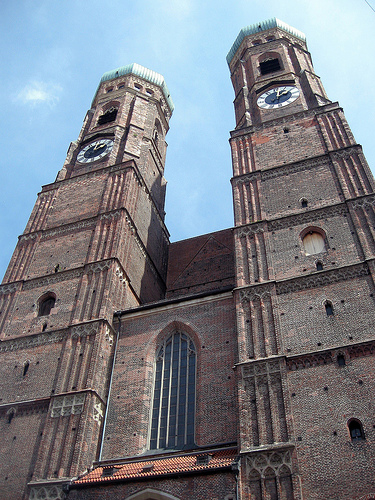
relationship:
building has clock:
[1, 18, 372, 500] [75, 138, 115, 163]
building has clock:
[1, 18, 372, 500] [256, 86, 299, 111]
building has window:
[1, 18, 372, 500] [144, 328, 200, 450]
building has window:
[1, 18, 372, 500] [38, 296, 55, 315]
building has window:
[1, 18, 372, 500] [348, 421, 364, 442]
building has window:
[1, 18, 372, 500] [336, 352, 346, 367]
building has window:
[1, 18, 372, 500] [324, 299, 335, 317]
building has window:
[1, 18, 372, 500] [316, 259, 324, 272]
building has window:
[1, 18, 372, 500] [300, 198, 309, 208]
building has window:
[1, 18, 372, 500] [283, 126, 290, 134]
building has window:
[1, 18, 372, 500] [256, 59, 284, 75]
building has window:
[1, 18, 372, 500] [7, 408, 15, 425]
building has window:
[1, 18, 372, 500] [22, 361, 30, 379]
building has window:
[1, 18, 372, 500] [40, 322, 50, 333]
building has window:
[1, 18, 372, 500] [53, 263, 61, 272]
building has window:
[1, 18, 372, 500] [96, 108, 118, 125]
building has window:
[1, 18, 372, 500] [153, 131, 161, 150]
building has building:
[1, 18, 372, 500] [1, 18, 374, 500]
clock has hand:
[75, 138, 115, 163] [94, 140, 100, 151]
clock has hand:
[256, 86, 299, 111] [278, 88, 291, 96]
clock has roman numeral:
[75, 138, 115, 163] [79, 157, 85, 163]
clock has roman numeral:
[256, 86, 299, 111] [267, 103, 274, 108]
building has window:
[1, 18, 374, 500] [119, 82, 127, 90]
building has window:
[1, 18, 374, 500] [266, 34, 276, 42]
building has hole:
[1, 18, 372, 500] [92, 412, 104, 426]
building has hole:
[1, 18, 372, 500] [93, 402, 105, 414]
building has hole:
[1, 18, 372, 500] [109, 334, 115, 346]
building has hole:
[1, 18, 372, 500] [104, 326, 110, 338]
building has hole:
[1, 18, 372, 500] [114, 268, 122, 276]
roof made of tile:
[68, 445, 238, 486] [72, 445, 241, 487]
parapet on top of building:
[100, 62, 177, 117] [1, 18, 374, 500]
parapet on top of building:
[222, 19, 307, 62] [1, 18, 374, 500]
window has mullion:
[144, 328, 200, 450] [155, 340, 167, 451]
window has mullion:
[144, 328, 200, 450] [163, 334, 175, 451]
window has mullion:
[144, 328, 200, 450] [174, 332, 182, 452]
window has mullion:
[144, 328, 200, 450] [182, 337, 192, 449]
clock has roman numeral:
[75, 138, 115, 163] [98, 153, 103, 156]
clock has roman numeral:
[256, 86, 299, 111] [289, 94, 302, 99]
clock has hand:
[75, 138, 115, 163] [96, 142, 108, 150]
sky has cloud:
[1, 1, 374, 283] [13, 77, 62, 117]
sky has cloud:
[1, 1, 374, 283] [176, 186, 205, 233]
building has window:
[1, 18, 374, 500] [283, 35, 291, 43]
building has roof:
[1, 18, 372, 500] [68, 445, 238, 486]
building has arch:
[1, 18, 372, 500] [148, 322, 203, 353]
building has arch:
[1, 18, 372, 500] [298, 225, 325, 236]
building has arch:
[1, 18, 372, 500] [37, 289, 59, 300]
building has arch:
[1, 18, 372, 500] [345, 416, 363, 425]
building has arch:
[1, 18, 372, 500] [256, 49, 284, 62]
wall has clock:
[1, 81, 172, 485] [75, 138, 115, 163]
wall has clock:
[233, 35, 375, 499] [256, 86, 299, 111]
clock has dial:
[75, 138, 115, 163] [76, 140, 111, 162]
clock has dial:
[256, 86, 299, 111] [256, 87, 300, 109]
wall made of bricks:
[1, 81, 172, 485] [24, 235, 94, 274]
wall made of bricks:
[233, 35, 375, 499] [254, 163, 339, 214]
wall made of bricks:
[68, 469, 237, 499] [166, 478, 230, 499]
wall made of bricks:
[163, 231, 235, 293] [170, 244, 204, 274]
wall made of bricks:
[98, 296, 238, 466] [190, 305, 235, 445]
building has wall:
[1, 18, 372, 500] [233, 35, 375, 499]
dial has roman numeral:
[76, 140, 111, 162] [104, 146, 112, 154]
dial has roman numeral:
[76, 140, 111, 162] [87, 141, 95, 151]